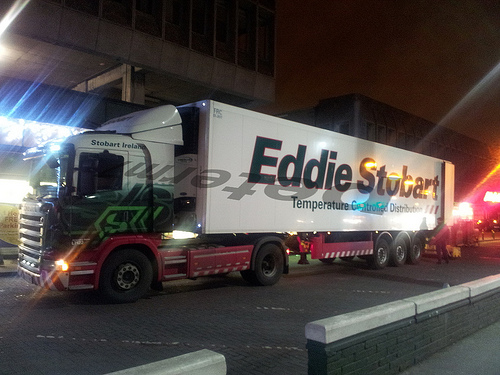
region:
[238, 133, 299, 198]
capital letter E on a transfer truck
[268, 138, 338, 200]
two d's on a transfer truck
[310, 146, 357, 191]
letter i on a transfer truck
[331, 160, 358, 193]
letter e on a transfer truck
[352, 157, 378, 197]
capital letter S on a transfer truck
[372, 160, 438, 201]
two letter t's on a transfer truck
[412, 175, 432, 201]
letter a on a transfer truck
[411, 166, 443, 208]
letter r on a transfer truck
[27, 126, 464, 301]
large white and red transfer truck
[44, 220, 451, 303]
five large tires on a transfer truck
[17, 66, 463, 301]
Large white semi truck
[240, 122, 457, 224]
Name of the company written on the side of the truck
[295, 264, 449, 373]
Brick wall alongside the street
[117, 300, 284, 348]
Street made up of stones and bricks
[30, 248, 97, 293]
Parking lights lit up on the truck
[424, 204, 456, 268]
Person standing next to the truck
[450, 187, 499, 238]
Bright lights shining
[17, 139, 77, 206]
Large windshield on the truck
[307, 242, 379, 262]
Red and white striped caution paints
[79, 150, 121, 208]
Large black side mirror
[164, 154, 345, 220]
reflection of words on side of truck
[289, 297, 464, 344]
large retaining wall on ground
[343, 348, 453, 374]
lines in black section of wall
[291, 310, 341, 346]
edge of gray wall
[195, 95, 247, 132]
small gray square spot on truck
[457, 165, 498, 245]
bright lights in the background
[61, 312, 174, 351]
faint white lines across the street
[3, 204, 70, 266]
large grill on front of truck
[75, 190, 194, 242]
green logo on side of truck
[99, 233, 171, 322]
large truck's black wheel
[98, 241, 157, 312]
the front tire is black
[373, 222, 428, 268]
a set of three tires under the rear of the trailer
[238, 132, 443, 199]
the trailer says Eddie Stobart on the side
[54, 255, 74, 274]
the headlight is illuminated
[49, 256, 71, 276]
the truck has headlights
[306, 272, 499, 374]
the retaining wall is brick and stone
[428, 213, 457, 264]
a man is standing near the rear of the trailer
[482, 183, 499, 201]
the red lights are blurry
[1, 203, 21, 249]
there is a yellow and black sign near the left of the picture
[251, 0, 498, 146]
the sky is dark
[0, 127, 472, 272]
A big truck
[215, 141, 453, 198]
the truck says "Eddie Stobart"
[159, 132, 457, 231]
The trailer is white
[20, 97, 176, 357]
The cab is white, green and red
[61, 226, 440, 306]
5 wheels on this side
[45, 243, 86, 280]
The lights are on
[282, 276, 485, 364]
A cement block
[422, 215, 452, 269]
A man standing by the truck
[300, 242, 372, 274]
White stripes on the side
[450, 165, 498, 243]
Red lights